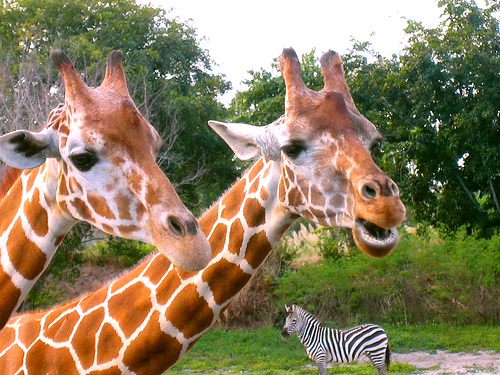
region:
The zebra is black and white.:
[268, 297, 403, 374]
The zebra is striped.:
[270, 296, 403, 373]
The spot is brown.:
[241, 193, 269, 230]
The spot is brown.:
[276, 174, 289, 204]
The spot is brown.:
[285, 180, 308, 212]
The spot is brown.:
[243, 226, 273, 273]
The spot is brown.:
[226, 215, 246, 262]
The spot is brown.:
[84, 185, 116, 222]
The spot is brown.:
[112, 185, 135, 223]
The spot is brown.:
[115, 220, 144, 237]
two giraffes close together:
[17, 49, 364, 374]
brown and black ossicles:
[275, 43, 350, 111]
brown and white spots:
[6, 169, 266, 371]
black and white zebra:
[301, 299, 403, 362]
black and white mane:
[288, 302, 351, 341]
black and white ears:
[280, 303, 295, 308]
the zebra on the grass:
[280, 303, 390, 374]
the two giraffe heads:
[0, 46, 405, 373]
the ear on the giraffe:
[0, 130, 56, 170]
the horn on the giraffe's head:
[50, 48, 87, 98]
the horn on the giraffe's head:
[102, 48, 127, 86]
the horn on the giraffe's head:
[277, 45, 305, 98]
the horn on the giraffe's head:
[320, 49, 345, 90]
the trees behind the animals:
[0, 0, 497, 327]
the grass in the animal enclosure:
[156, 323, 498, 374]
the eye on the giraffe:
[68, 151, 95, 166]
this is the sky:
[226, 12, 296, 48]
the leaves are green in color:
[416, 37, 468, 121]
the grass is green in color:
[418, 311, 473, 338]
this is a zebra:
[285, 301, 382, 371]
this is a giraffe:
[193, 83, 433, 277]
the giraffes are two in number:
[14, 40, 313, 322]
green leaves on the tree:
[437, 78, 497, 123]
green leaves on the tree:
[451, 169, 482, 210]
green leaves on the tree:
[470, 149, 492, 189]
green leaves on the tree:
[412, 106, 432, 134]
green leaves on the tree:
[460, 163, 477, 197]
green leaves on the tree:
[457, 58, 488, 116]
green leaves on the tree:
[447, 45, 489, 86]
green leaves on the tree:
[121, 42, 176, 82]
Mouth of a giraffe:
[359, 213, 408, 251]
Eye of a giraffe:
[275, 135, 308, 167]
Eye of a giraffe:
[361, 130, 386, 155]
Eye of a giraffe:
[67, 139, 98, 174]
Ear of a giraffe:
[2, 124, 58, 173]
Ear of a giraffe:
[3, 126, 53, 170]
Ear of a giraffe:
[203, 115, 264, 165]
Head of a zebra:
[275, 300, 312, 347]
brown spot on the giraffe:
[240, 227, 273, 274]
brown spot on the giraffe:
[236, 193, 268, 231]